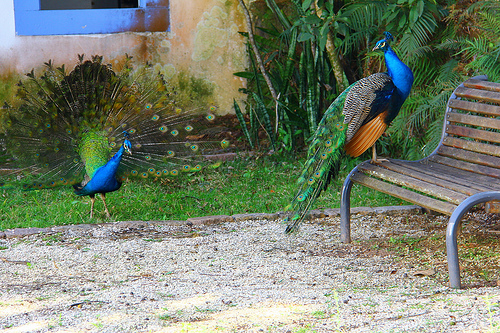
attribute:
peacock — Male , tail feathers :
[21, 63, 251, 218]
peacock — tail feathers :
[259, 30, 422, 238]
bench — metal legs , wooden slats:
[325, 72, 484, 265]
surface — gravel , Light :
[97, 246, 387, 302]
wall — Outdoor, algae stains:
[177, 10, 254, 102]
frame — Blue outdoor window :
[25, 20, 172, 47]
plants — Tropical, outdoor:
[5, 77, 326, 195]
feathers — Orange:
[348, 110, 390, 159]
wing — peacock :
[310, 94, 391, 219]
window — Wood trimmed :
[10, 4, 180, 46]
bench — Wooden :
[336, 76, 484, 279]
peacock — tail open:
[24, 51, 263, 208]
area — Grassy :
[2, 7, 251, 149]